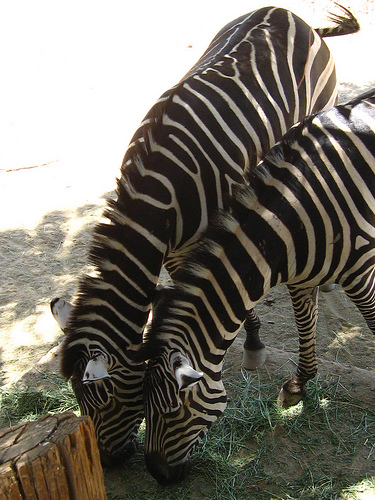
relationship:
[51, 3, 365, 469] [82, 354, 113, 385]
zebra has ear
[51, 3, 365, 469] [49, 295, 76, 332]
zebra has ear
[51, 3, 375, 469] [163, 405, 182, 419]
zebra has eye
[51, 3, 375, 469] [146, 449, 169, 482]
zebra has nose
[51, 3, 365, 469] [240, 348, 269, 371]
zebra has hoof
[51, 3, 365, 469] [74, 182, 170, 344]
zebra has neck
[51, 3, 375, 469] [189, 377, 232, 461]
zebra has jaw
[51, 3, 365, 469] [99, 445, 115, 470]
zebra has nose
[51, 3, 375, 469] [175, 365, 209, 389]
zebra has ear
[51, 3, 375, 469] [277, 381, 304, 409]
zebra has hoof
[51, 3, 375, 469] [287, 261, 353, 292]
zebra has stomach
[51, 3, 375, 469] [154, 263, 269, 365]
zebra has neck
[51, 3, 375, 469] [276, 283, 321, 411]
zebra has leg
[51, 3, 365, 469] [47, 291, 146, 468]
zebra has head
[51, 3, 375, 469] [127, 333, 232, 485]
zebra has head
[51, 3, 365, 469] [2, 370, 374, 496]
zebra grazes hay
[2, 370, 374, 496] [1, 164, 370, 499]
hay on ground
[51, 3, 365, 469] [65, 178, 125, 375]
zebra has mane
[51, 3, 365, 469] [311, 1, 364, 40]
zebra has tail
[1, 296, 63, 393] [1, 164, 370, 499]
sunlight on ground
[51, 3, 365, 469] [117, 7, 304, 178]
zebra has back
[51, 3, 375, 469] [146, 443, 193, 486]
zebra has snout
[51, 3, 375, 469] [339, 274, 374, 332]
zebra has leg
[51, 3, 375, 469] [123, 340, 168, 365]
zebra has ear